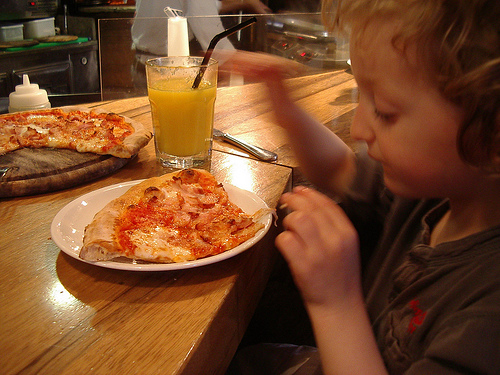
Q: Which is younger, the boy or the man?
A: The boy is younger than the man.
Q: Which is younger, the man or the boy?
A: The boy is younger than the man.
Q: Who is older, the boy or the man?
A: The man is older than the boy.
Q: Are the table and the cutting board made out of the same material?
A: Yes, both the table and the cutting board are made of wood.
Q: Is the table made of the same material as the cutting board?
A: Yes, both the table and the cutting board are made of wood.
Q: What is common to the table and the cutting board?
A: The material, both the table and the cutting board are wooden.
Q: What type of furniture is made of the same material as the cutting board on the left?
A: The table is made of the same material as the cutting board.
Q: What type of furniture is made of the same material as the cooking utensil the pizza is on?
A: The table is made of the same material as the cutting board.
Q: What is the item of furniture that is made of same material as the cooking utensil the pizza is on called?
A: The piece of furniture is a table.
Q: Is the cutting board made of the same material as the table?
A: Yes, both the cutting board and the table are made of wood.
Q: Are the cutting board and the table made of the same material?
A: Yes, both the cutting board and the table are made of wood.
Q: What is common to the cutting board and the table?
A: The material, both the cutting board and the table are wooden.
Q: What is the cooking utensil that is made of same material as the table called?
A: The cooking utensil is a cutting board.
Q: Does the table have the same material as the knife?
A: No, the table is made of wood and the knife is made of metal.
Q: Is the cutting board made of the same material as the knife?
A: No, the cutting board is made of wood and the knife is made of metal.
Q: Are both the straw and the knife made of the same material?
A: No, the straw is made of plastic and the knife is made of metal.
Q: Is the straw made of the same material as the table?
A: No, the straw is made of plastic and the table is made of wood.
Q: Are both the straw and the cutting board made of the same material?
A: No, the straw is made of plastic and the cutting board is made of wood.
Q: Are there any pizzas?
A: Yes, there is a pizza.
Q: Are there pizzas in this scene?
A: Yes, there is a pizza.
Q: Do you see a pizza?
A: Yes, there is a pizza.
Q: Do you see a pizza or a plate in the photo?
A: Yes, there is a pizza.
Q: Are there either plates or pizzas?
A: Yes, there is a pizza.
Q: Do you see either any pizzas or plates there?
A: Yes, there is a pizza.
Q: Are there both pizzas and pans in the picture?
A: No, there is a pizza but no pans.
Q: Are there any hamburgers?
A: No, there are no hamburgers.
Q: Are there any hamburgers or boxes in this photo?
A: No, there are no hamburgers or boxes.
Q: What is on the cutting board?
A: The pizza is on the cutting board.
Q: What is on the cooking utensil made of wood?
A: The pizza is on the cutting board.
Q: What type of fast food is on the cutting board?
A: The food is a pizza.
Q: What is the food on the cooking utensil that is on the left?
A: The food is a pizza.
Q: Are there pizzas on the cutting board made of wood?
A: Yes, there is a pizza on the cutting board.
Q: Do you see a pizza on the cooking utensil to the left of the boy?
A: Yes, there is a pizza on the cutting board.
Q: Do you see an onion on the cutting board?
A: No, there is a pizza on the cutting board.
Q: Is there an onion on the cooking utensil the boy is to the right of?
A: No, there is a pizza on the cutting board.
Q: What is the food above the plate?
A: The food is a pizza.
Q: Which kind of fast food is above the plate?
A: The food is a pizza.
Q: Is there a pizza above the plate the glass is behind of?
A: Yes, there is a pizza above the plate.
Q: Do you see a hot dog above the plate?
A: No, there is a pizza above the plate.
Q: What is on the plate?
A: The pizza is on the plate.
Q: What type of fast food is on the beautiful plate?
A: The food is a pizza.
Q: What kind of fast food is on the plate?
A: The food is a pizza.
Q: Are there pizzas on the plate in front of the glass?
A: Yes, there is a pizza on the plate.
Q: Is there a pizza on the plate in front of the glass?
A: Yes, there is a pizza on the plate.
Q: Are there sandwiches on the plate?
A: No, there is a pizza on the plate.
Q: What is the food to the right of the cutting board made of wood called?
A: The food is a pizza.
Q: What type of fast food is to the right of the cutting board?
A: The food is a pizza.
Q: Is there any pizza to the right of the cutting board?
A: Yes, there is a pizza to the right of the cutting board.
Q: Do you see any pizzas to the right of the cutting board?
A: Yes, there is a pizza to the right of the cutting board.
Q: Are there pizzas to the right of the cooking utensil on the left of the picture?
A: Yes, there is a pizza to the right of the cutting board.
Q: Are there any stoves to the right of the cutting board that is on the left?
A: No, there is a pizza to the right of the cutting board.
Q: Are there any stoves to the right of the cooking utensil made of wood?
A: No, there is a pizza to the right of the cutting board.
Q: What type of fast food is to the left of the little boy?
A: The food is a pizza.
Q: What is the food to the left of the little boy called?
A: The food is a pizza.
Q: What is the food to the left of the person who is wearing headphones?
A: The food is a pizza.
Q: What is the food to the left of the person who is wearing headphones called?
A: The food is a pizza.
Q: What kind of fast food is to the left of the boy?
A: The food is a pizza.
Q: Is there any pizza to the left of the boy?
A: Yes, there is a pizza to the left of the boy.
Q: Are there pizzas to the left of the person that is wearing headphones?
A: Yes, there is a pizza to the left of the boy.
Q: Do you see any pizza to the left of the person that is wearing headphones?
A: Yes, there is a pizza to the left of the boy.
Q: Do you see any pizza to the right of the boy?
A: No, the pizza is to the left of the boy.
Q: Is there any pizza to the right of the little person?
A: No, the pizza is to the left of the boy.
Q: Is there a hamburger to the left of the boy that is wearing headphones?
A: No, there is a pizza to the left of the boy.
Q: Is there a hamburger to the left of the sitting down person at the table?
A: No, there is a pizza to the left of the boy.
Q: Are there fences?
A: No, there are no fences.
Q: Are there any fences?
A: No, there are no fences.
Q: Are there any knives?
A: Yes, there is a knife.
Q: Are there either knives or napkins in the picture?
A: Yes, there is a knife.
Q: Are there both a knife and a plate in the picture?
A: Yes, there are both a knife and a plate.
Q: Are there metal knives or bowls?
A: Yes, there is a metal knife.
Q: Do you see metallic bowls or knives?
A: Yes, there is a metal knife.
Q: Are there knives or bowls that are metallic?
A: Yes, the knife is metallic.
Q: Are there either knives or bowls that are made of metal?
A: Yes, the knife is made of metal.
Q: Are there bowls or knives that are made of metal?
A: Yes, the knife is made of metal.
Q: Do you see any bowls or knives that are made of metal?
A: Yes, the knife is made of metal.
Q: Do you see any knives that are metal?
A: Yes, there is a metal knife.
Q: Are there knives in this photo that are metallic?
A: Yes, there is a knife that is metallic.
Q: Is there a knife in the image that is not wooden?
A: Yes, there is a metallic knife.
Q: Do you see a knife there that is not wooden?
A: Yes, there is a metallic knife.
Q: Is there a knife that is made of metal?
A: Yes, there is a knife that is made of metal.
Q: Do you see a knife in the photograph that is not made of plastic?
A: Yes, there is a knife that is made of metal.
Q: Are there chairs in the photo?
A: No, there are no chairs.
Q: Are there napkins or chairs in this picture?
A: No, there are no chairs or napkins.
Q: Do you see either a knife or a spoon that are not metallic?
A: No, there is a knife but it is metallic.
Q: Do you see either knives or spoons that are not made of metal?
A: No, there is a knife but it is made of metal.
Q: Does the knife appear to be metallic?
A: Yes, the knife is metallic.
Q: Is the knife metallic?
A: Yes, the knife is metallic.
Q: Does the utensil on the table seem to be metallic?
A: Yes, the knife is metallic.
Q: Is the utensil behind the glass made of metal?
A: Yes, the knife is made of metal.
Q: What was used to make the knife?
A: The knife is made of metal.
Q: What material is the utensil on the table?
A: The knife is made of metal.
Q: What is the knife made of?
A: The knife is made of metal.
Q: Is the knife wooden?
A: No, the knife is metallic.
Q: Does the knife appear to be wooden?
A: No, the knife is metallic.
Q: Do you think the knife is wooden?
A: No, the knife is metallic.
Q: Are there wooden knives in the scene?
A: No, there is a knife but it is metallic.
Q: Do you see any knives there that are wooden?
A: No, there is a knife but it is metallic.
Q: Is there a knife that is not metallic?
A: No, there is a knife but it is metallic.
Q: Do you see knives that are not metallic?
A: No, there is a knife but it is metallic.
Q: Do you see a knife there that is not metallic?
A: No, there is a knife but it is metallic.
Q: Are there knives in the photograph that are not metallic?
A: No, there is a knife but it is metallic.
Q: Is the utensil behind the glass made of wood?
A: No, the knife is made of metal.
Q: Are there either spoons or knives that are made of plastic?
A: No, there is a knife but it is made of metal.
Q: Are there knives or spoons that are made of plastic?
A: No, there is a knife but it is made of metal.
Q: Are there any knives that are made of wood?
A: No, there is a knife but it is made of metal.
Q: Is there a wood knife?
A: No, there is a knife but it is made of metal.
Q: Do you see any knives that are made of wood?
A: No, there is a knife but it is made of metal.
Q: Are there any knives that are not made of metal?
A: No, there is a knife but it is made of metal.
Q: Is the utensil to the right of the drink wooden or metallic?
A: The knife is metallic.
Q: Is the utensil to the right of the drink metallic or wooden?
A: The knife is metallic.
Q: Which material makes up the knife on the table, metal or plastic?
A: The knife is made of metal.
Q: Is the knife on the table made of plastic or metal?
A: The knife is made of metal.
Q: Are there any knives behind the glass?
A: Yes, there is a knife behind the glass.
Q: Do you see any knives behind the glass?
A: Yes, there is a knife behind the glass.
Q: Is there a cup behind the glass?
A: No, there is a knife behind the glass.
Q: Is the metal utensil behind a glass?
A: Yes, the knife is behind a glass.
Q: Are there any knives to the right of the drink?
A: Yes, there is a knife to the right of the drink.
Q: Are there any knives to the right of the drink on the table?
A: Yes, there is a knife to the right of the drink.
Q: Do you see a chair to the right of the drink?
A: No, there is a knife to the right of the drink.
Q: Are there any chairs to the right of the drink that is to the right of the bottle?
A: No, there is a knife to the right of the drink.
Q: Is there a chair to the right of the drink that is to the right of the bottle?
A: No, there is a knife to the right of the drink.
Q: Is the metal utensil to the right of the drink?
A: Yes, the knife is to the right of the drink.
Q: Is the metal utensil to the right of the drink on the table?
A: Yes, the knife is to the right of the drink.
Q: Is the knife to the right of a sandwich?
A: No, the knife is to the right of the drink.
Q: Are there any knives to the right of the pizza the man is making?
A: Yes, there is a knife to the right of the pizza.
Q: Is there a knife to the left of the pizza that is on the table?
A: No, the knife is to the right of the pizza.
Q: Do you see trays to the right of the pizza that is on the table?
A: No, there is a knife to the right of the pizza.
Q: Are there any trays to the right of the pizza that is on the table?
A: No, there is a knife to the right of the pizza.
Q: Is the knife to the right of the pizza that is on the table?
A: Yes, the knife is to the right of the pizza.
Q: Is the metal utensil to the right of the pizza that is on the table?
A: Yes, the knife is to the right of the pizza.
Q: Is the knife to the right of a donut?
A: No, the knife is to the right of the pizza.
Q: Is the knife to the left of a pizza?
A: No, the knife is to the right of a pizza.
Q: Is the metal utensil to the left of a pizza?
A: No, the knife is to the right of a pizza.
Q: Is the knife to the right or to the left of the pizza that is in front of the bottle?
A: The knife is to the right of the pizza.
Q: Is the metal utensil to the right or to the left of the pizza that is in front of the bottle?
A: The knife is to the right of the pizza.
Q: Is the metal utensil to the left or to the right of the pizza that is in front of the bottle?
A: The knife is to the right of the pizza.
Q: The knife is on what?
A: The knife is on the table.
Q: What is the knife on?
A: The knife is on the table.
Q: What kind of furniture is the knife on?
A: The knife is on the table.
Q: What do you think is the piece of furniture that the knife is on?
A: The piece of furniture is a table.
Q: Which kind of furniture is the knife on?
A: The knife is on the table.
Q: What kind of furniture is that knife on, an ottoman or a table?
A: The knife is on a table.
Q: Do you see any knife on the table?
A: Yes, there is a knife on the table.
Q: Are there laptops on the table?
A: No, there is a knife on the table.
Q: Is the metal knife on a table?
A: Yes, the knife is on a table.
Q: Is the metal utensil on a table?
A: Yes, the knife is on a table.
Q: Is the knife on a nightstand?
A: No, the knife is on a table.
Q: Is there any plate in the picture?
A: Yes, there is a plate.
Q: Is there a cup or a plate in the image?
A: Yes, there is a plate.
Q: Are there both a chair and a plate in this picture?
A: No, there is a plate but no chairs.